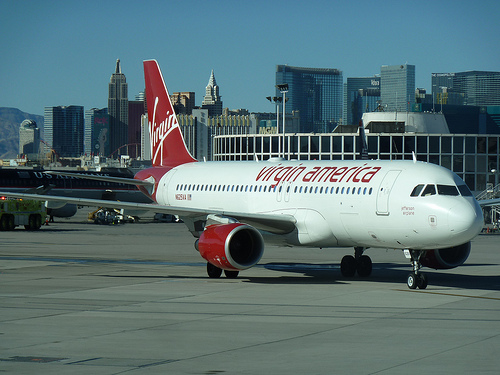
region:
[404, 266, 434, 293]
tires on a plane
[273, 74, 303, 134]
a light on a pole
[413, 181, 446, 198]
windows on the front of the plane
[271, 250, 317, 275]
water under the plane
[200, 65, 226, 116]
a tall building in the distance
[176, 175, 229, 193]
windows on the side of the plane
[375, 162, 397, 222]
a door on the plane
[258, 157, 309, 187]
red letters on the plane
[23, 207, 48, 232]
a tire on a truck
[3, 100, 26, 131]
mountains in the distance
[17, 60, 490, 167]
a city sky line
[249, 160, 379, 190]
the company name of the plane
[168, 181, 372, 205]
a long row of windows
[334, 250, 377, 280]
a plane's landing gear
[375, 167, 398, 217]
a small metal door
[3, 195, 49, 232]
a large airport vehicle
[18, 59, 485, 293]
a red and white plane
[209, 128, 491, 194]
a building with glass walls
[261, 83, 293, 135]
a few large spotlights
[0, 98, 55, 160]
a distant mountain side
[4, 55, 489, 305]
Airplane from Virgin America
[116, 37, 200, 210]
Tail fin is red with logo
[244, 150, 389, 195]
Virgin America logo on side of plane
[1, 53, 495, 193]
cityscape in background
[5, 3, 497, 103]
clear skies on a sunny day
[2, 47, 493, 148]
tall skyscrapers in the city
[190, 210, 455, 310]
Landing gear is down on plane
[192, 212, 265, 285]
Jet engine is red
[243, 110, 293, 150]
MGM Studios logo on building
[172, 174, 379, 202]
tiny-looking passenger compartment windows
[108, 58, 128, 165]
building behind parked plane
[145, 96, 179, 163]
"virgin" written on tail of plane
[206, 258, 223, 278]
Black wheel on plane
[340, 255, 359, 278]
black wheel on plane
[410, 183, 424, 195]
window on front of airplane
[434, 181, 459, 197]
window in front of airplane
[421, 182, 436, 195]
window in front of plane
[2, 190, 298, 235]
wing on the side of plane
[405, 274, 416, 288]
small wheel in front of plane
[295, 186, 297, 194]
window on side of plane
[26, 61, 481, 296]
a white and red airplane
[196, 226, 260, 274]
a red turbine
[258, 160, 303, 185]
the word virgin in red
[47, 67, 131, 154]
some buildings in the distance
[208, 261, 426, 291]
the landing gear of the plane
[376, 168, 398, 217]
the exit door of the plane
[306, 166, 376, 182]
the word america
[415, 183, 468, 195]
the cockpit of the plane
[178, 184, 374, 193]
the passengers windows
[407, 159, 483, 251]
the front view of the plane